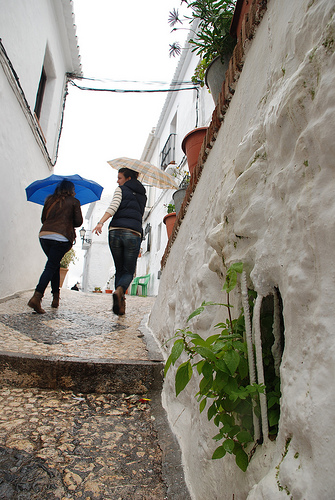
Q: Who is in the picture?
A: Women.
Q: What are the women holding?
A: Umbrellas.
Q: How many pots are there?
A: 6.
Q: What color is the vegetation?
A: Green.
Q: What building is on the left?
A: House.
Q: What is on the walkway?
A: A step.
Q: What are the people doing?
A: Walking.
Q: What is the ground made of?
A: Rock and gravel.